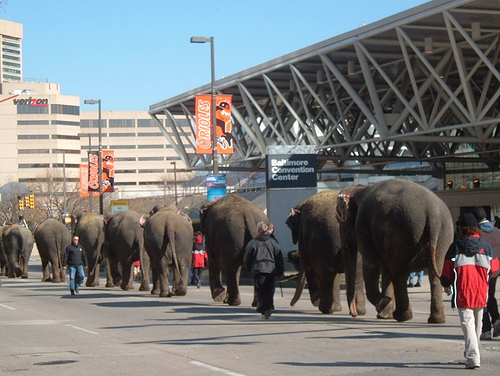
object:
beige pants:
[457, 307, 484, 365]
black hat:
[455, 211, 479, 226]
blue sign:
[206, 172, 227, 203]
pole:
[207, 40, 217, 183]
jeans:
[69, 264, 84, 289]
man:
[62, 234, 87, 296]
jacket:
[62, 244, 88, 268]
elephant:
[285, 190, 365, 318]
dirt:
[312, 191, 339, 207]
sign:
[192, 93, 236, 154]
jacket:
[439, 234, 500, 309]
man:
[438, 213, 499, 369]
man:
[466, 203, 500, 339]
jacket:
[468, 221, 500, 278]